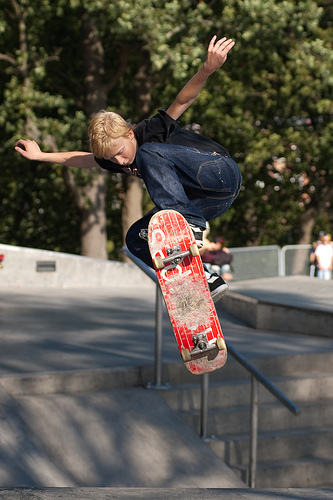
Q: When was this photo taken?
A: During the day.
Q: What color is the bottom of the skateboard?
A: Red.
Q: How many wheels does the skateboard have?
A: 4.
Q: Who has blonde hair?
A: The boy on the skateboard.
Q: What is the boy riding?
A: Skateboard.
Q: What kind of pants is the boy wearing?
A: Jeans.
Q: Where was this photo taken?
A: In a skate park.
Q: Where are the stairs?
A: Behind the boy.